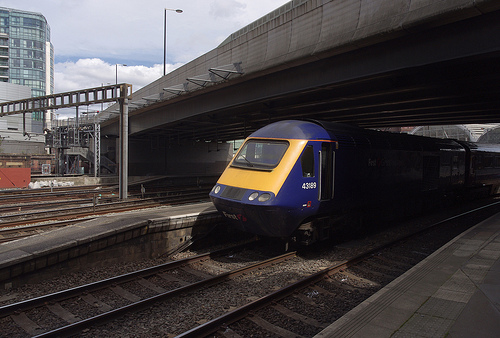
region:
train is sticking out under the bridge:
[49, 2, 498, 245]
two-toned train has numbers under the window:
[209, 120, 495, 250]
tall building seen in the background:
[1, 4, 54, 134]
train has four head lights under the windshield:
[206, 116, 497, 252]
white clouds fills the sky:
[0, 1, 287, 119]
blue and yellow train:
[211, 111, 420, 243]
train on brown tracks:
[16, 233, 284, 330]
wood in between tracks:
[16, 226, 289, 329]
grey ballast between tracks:
[158, 228, 286, 313]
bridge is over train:
[176, 33, 478, 93]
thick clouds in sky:
[99, 7, 154, 70]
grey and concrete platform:
[371, 251, 495, 329]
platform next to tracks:
[388, 266, 493, 337]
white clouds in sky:
[0, 0, 286, 120]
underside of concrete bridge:
[96, 0, 496, 141]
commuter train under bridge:
[210, 21, 495, 241]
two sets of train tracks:
[0, 198, 490, 334]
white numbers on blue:
[302, 179, 318, 189]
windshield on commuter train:
[234, 137, 289, 169]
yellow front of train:
[219, 134, 304, 194]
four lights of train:
[211, 184, 270, 204]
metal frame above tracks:
[1, 79, 130, 217]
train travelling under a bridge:
[208, 116, 498, 256]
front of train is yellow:
[215, 137, 306, 195]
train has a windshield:
[231, 137, 288, 172]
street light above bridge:
[161, 7, 183, 76]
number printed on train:
[301, 179, 318, 189]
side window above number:
[300, 144, 314, 176]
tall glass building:
[0, 8, 53, 134]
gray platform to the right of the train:
[306, 209, 498, 337]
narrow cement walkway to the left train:
[0, 197, 220, 280]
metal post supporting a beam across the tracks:
[116, 83, 131, 198]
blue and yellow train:
[217, 120, 493, 230]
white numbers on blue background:
[298, 184, 320, 191]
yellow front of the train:
[220, 137, 300, 199]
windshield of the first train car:
[231, 141, 282, 163]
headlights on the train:
[213, 185, 266, 205]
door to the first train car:
[315, 151, 336, 201]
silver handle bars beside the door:
[315, 150, 336, 203]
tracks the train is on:
[4, 243, 245, 336]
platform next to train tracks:
[335, 209, 497, 335]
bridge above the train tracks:
[85, 3, 494, 179]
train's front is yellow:
[224, 135, 297, 197]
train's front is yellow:
[215, 135, 293, 197]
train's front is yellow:
[201, 135, 300, 198]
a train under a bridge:
[193, 1, 495, 267]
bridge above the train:
[65, 11, 499, 150]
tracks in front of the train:
[3, 226, 258, 329]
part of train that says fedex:
[220, 207, 248, 229]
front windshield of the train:
[236, 136, 287, 167]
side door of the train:
[317, 142, 337, 199]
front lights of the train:
[209, 181, 276, 203]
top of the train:
[264, 114, 499, 151]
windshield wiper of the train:
[237, 153, 256, 170]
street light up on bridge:
[156, 4, 196, 79]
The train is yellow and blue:
[198, 103, 410, 278]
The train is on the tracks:
[107, 67, 406, 318]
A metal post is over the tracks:
[2, 51, 175, 259]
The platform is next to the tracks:
[282, 180, 497, 333]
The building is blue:
[5, 3, 85, 180]